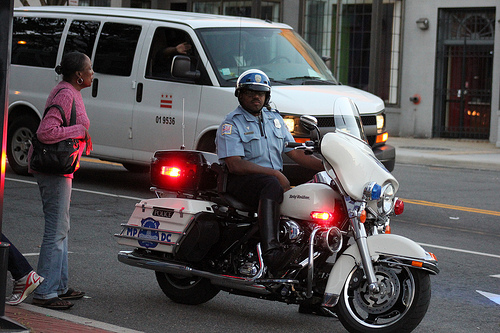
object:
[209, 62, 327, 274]
man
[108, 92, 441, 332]
bike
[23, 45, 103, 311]
woman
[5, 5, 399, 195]
van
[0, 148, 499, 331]
road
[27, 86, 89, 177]
bag